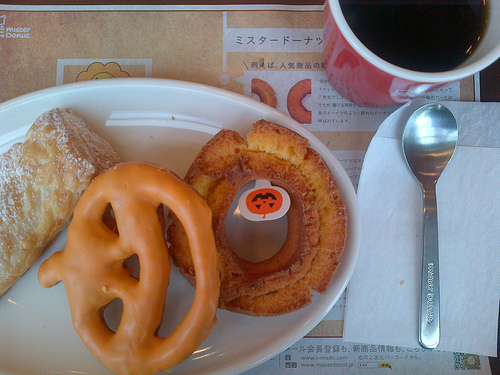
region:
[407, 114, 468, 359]
A teaspoon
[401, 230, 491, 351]
A teaspoon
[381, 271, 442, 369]
A teaspoon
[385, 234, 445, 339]
A teaspoon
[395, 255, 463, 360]
A teaspoon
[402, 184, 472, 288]
A teaspoon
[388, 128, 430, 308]
A teaspoon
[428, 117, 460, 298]
A teaspoon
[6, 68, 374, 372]
Plate filled with pastry.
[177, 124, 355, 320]
Cake doughnut on white plate.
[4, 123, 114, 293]
Powered sugar covered cream puff.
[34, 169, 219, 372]
Icing covered jack o lanterned shaped pretzel.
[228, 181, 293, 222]
Jack o lantern sticker under doughnut.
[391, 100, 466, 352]
Spoon lying on napkin on table.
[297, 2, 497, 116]
Coffe cup sitting on table.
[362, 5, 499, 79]
Black coffee in cup sitting on table.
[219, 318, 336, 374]
Edge of white plate on table.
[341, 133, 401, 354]
White napkin sitting on table.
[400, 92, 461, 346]
A silver spoon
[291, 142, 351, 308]
a sugar donut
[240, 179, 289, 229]
An orange pumpkin face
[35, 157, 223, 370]
a coated pretzel with the face of a pumpkin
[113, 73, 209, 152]
The side of a white plate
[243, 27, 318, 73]
Chinese writing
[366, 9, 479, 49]
Black coffee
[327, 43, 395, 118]
red and white mug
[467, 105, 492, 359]
a white paper napkin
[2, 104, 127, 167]
White powdered pastry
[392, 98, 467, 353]
a silver spoon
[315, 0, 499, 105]
a cup of coffee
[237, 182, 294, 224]
a jack-o-lantern decoration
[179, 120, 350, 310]
a delicious looking doughnut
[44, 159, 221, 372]
a jack-o-lantern shaped pastry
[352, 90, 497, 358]
a white paper napkin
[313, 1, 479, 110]
a red coffee cup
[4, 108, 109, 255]
a tasty looking pastry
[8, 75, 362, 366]
a plate of breakfast pastries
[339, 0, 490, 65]
black coffee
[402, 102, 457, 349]
the silver spoon is on a napkin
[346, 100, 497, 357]
the folded napkin is white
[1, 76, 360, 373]
the white plate is oval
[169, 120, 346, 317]
the donut is plain and brownish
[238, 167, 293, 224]
an upside down paper pumpkin is in the donut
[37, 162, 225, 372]
a pretzel is in the shape of a pumpkin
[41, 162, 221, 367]
the pretzel has a happy face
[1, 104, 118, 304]
a danish is next to the pretzel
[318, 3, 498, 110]
near the plate is a red cup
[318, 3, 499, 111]
the cup has a white trim